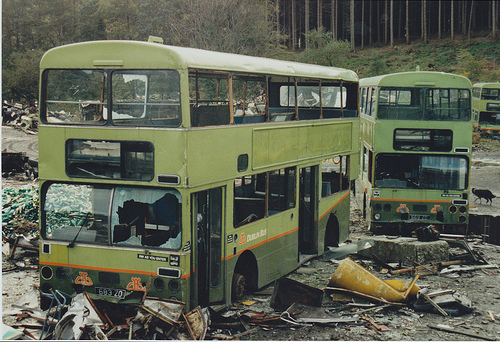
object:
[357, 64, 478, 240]
busses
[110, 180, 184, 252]
window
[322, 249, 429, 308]
junk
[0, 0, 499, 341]
picture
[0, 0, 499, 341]
junk yard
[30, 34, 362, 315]
bus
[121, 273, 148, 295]
bus logo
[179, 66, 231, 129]
windows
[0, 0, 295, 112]
trees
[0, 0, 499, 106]
plants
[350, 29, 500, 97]
grass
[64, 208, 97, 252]
windshield wiiper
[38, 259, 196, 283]
stripe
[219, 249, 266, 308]
tires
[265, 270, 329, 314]
scrap metal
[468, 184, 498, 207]
dog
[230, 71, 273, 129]
windows